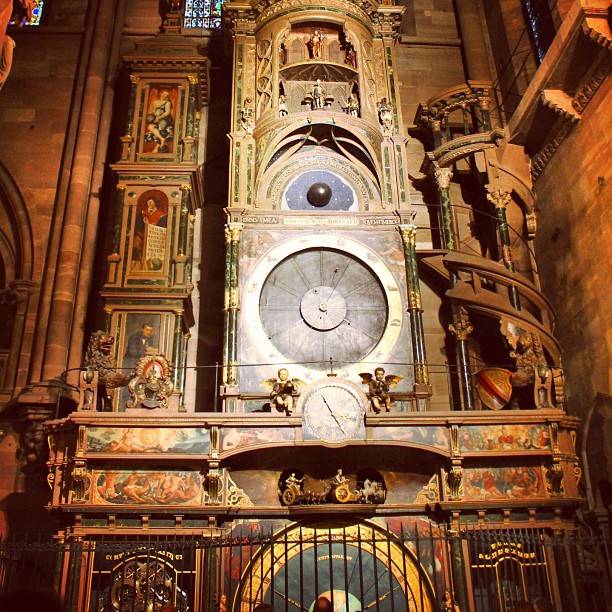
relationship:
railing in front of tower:
[14, 528, 611, 609] [215, 7, 443, 428]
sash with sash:
[476, 368, 512, 410] [476, 369, 511, 406]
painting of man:
[125, 189, 171, 278] [136, 193, 166, 249]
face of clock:
[257, 247, 390, 370] [236, 224, 414, 394]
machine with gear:
[111, 557, 178, 610] [145, 561, 163, 579]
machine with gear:
[111, 557, 178, 610] [126, 561, 143, 583]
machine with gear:
[111, 557, 178, 610] [146, 583, 171, 609]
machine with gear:
[111, 557, 178, 610] [113, 583, 139, 610]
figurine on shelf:
[344, 45, 357, 67] [279, 57, 362, 83]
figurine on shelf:
[303, 27, 324, 59] [279, 57, 362, 83]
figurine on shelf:
[281, 38, 293, 64] [279, 57, 362, 83]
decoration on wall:
[279, 469, 334, 509] [0, 2, 589, 610]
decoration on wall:
[333, 467, 384, 504] [0, 2, 589, 610]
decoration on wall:
[358, 366, 401, 416] [0, 2, 589, 610]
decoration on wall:
[260, 366, 306, 416] [0, 2, 589, 610]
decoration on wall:
[509, 327, 546, 388] [0, 2, 589, 610]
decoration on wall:
[127, 350, 177, 412] [0, 2, 589, 610]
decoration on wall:
[83, 327, 135, 408] [0, 2, 589, 610]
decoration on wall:
[434, 165, 460, 254] [0, 2, 589, 610]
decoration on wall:
[122, 176, 185, 286] [0, 2, 589, 610]